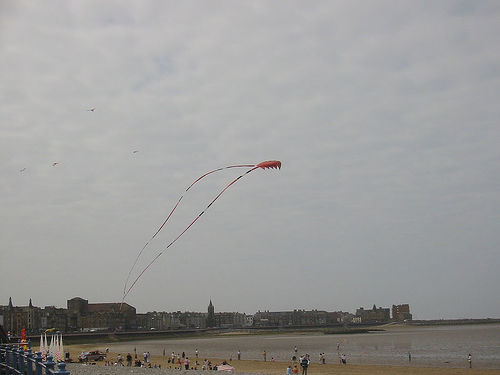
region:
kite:
[232, 141, 290, 185]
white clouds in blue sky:
[341, 228, 392, 249]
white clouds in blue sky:
[392, 122, 409, 154]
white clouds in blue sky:
[250, 236, 292, 284]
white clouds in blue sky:
[407, 29, 449, 104]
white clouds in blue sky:
[185, 66, 217, 91]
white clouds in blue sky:
[291, 28, 353, 92]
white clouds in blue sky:
[347, 218, 405, 252]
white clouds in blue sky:
[90, 91, 150, 159]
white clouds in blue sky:
[101, 209, 166, 253]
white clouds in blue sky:
[335, 136, 370, 156]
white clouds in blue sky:
[377, 169, 424, 201]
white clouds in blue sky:
[191, 46, 221, 58]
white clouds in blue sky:
[365, 12, 437, 87]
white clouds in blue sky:
[41, 52, 118, 99]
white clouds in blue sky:
[94, 146, 145, 200]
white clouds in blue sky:
[242, 199, 313, 237]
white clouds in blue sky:
[304, 199, 419, 257]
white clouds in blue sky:
[158, 26, 238, 93]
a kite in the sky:
[246, 139, 302, 205]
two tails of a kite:
[183, 152, 236, 212]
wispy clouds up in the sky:
[138, 59, 208, 123]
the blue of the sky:
[386, 192, 458, 247]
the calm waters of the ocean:
[416, 319, 465, 359]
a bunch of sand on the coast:
[347, 358, 359, 370]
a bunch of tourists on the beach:
[132, 343, 177, 368]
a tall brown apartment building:
[61, 289, 108, 328]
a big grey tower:
[198, 300, 221, 321]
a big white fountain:
[23, 328, 74, 355]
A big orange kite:
[10, 48, 479, 365]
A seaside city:
[55, 267, 408, 336]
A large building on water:
[49, 276, 139, 336]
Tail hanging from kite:
[133, 160, 250, 305]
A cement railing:
[5, 342, 64, 374]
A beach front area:
[202, 328, 428, 373]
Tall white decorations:
[39, 334, 84, 363]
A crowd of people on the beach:
[121, 342, 205, 374]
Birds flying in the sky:
[42, 72, 217, 182]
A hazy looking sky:
[81, 69, 381, 250]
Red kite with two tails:
[119, 159, 281, 309]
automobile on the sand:
[78, 350, 107, 359]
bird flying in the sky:
[85, 105, 97, 115]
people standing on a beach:
[103, 346, 346, 373]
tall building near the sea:
[208, 299, 215, 327]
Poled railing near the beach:
[0, 343, 70, 374]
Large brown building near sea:
[66, 295, 137, 329]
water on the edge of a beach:
[93, 325, 498, 368]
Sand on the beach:
[28, 342, 499, 374]